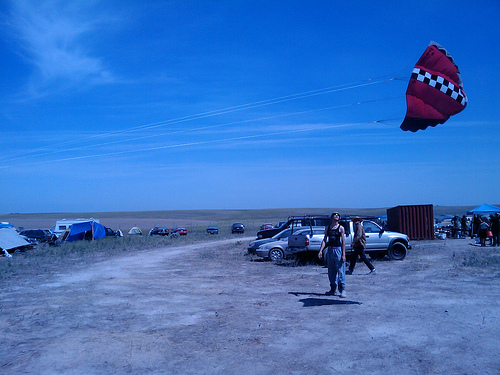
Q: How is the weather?
A: Sunny.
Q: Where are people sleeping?
A: In tents.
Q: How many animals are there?
A: None.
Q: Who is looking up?
A: The man with baggy pants.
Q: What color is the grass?
A: Brown.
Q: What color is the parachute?
A: Red.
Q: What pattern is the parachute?
A: Checkered.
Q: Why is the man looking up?
A: To see the parachute.